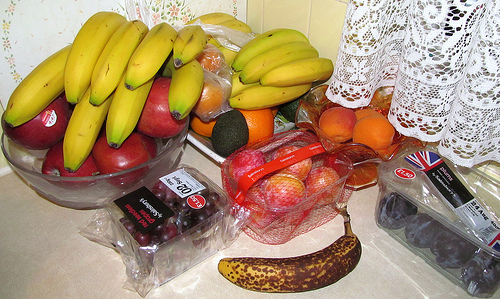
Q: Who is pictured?
A: No one.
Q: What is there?
A: Fruit.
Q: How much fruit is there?
A: Lots of fruit.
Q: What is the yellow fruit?
A: Bananas.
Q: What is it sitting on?
A: Counter.